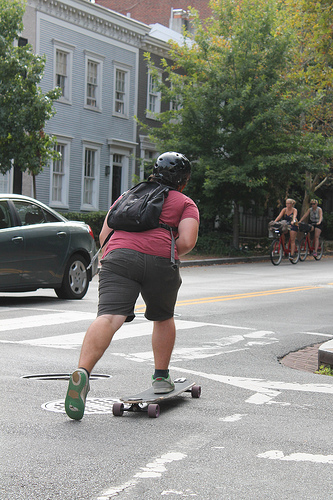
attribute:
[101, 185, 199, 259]
t-shirt — red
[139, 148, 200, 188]
helmet — black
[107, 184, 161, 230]
backpack — black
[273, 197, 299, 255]
woman — blonde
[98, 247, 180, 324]
pants — short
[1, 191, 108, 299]
car — gray, four-door, sedan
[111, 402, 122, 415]
wheel — purple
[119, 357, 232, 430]
skateboard — black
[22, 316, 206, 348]
line — white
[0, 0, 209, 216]
building — gray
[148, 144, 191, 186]
helmet — black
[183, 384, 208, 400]
wheel — purple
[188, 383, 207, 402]
wheel — purple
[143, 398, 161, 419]
wheel — purple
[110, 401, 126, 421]
wheel — purple